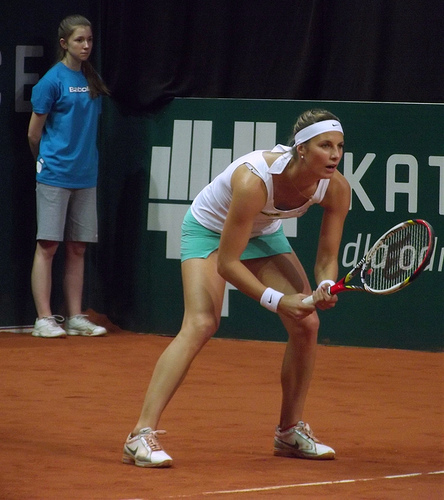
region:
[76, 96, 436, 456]
woman playing tennis on court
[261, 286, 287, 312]
white nike wrist band on woman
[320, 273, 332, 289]
white wrist band on woman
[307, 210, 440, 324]
red and white racket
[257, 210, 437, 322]
hands hold tennis racket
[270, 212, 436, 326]
tennis racket in hands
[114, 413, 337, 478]
white nike tennis shoes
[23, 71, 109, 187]
blue t-shirt on woman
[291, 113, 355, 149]
white nike head band on woman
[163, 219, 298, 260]
blue tennis uniform on woman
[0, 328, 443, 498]
red looking dirt ground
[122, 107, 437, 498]
a woman with a tennis racket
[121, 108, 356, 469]
a woman bend over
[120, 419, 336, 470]
white tennis shoes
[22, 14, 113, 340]
a girl standing on the side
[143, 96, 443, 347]
a green and white advertising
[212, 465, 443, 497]
a white line in the red dirt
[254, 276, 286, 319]
white Nike wrist band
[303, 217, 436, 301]
tennis racket with a black W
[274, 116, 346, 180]
white Nike head band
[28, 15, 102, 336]
girl in blue shirt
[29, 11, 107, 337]
girl in gray shorts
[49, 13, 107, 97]
long hair on chest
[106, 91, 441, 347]
green wall with white logo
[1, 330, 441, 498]
white line on clay court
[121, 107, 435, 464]
tennis player in ready position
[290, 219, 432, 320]
two hands on tennis racket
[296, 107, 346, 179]
white band on head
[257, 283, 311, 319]
white band on wrist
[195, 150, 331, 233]
white tank top on body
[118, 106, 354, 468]
Woman playing tennis on court.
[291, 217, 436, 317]
Woman holding tennis racket in hands.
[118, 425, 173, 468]
Woman wearing white and pink Nike tennis shoe on foot.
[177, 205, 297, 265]
Woman wearing aqua tennis skirt.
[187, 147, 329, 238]
Woman dressed in white tank top.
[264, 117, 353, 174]
Woman wearing white sweatband around head.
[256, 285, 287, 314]
Woman wearing white Nike band around wrist.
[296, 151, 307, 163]
Woman wearing earring in ear.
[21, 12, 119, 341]
Young girl standing in background behind tennis player.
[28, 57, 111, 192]
Young girl wearing blue t-shirt.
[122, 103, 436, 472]
A woman playing tennis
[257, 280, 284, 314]
A white arm band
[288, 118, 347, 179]
White headband on woman's head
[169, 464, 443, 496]
A white line on the court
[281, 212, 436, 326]
Tennis racket in two hands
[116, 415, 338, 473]
A pair of white sneakers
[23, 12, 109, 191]
Woman wearing a blue shirt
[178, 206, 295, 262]
A tourquoise blue tennis skirt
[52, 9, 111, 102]
Brown hair on woman's head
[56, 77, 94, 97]
White word on blue shirt